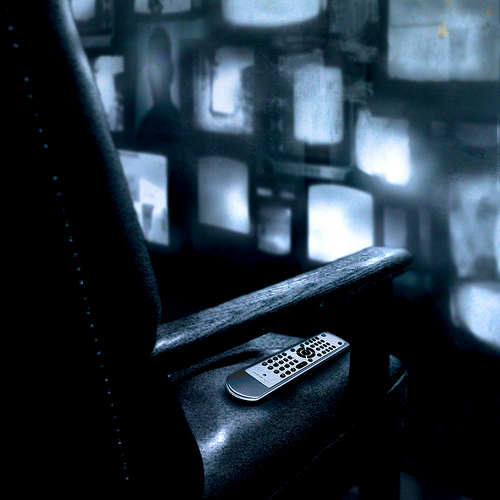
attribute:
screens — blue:
[92, 7, 486, 352]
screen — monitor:
[294, 181, 389, 265]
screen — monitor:
[119, 150, 170, 251]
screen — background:
[221, 0, 325, 27]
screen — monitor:
[301, 184, 388, 264]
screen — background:
[323, 196, 396, 311]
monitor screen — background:
[135, 31, 177, 120]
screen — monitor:
[346, 108, 426, 194]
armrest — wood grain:
[153, 239, 415, 472]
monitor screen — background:
[287, 60, 345, 155]